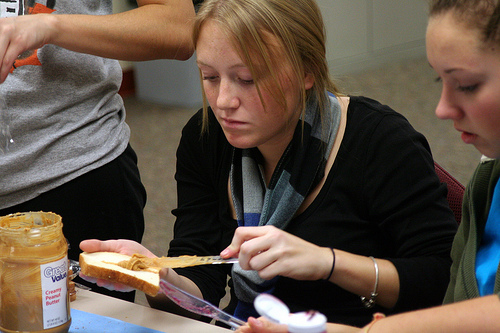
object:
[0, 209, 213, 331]
butter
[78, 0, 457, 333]
girl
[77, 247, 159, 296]
sandwich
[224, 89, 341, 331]
scarf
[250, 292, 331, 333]
lid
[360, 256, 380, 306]
bracelet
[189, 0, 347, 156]
girl hair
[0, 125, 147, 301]
black pant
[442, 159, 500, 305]
blue shirt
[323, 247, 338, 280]
black bracelet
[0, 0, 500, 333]
three people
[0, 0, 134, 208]
t-shirt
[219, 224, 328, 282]
hand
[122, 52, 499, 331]
black top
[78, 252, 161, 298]
bread slices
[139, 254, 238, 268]
knife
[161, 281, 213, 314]
jam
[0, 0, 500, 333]
showl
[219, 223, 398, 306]
arm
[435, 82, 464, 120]
nose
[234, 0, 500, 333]
lady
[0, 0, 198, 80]
arm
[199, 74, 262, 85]
eyelashes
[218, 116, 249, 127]
mouth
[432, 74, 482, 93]
eyelashes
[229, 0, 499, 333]
woman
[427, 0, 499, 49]
hair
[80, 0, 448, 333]
woman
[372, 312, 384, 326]
bracelet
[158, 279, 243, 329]
knife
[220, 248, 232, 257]
fingernails